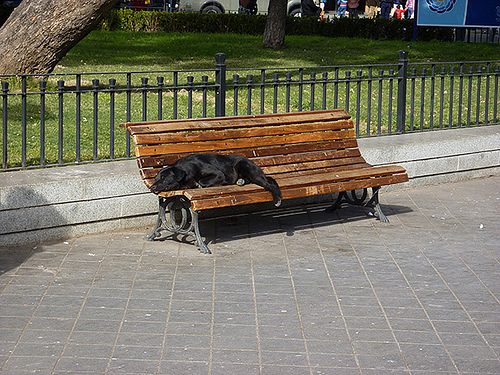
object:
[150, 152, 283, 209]
dog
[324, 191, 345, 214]
leg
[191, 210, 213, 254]
leg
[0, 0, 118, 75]
tree trunk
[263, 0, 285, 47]
tree trunk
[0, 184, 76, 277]
shadow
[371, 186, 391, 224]
leg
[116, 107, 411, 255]
bench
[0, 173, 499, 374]
ground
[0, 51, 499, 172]
fence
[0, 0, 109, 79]
tree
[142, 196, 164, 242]
leg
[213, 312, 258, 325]
tile